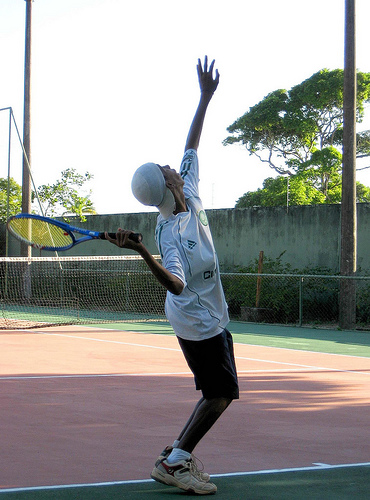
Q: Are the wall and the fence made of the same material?
A: No, the wall is made of cement and the fence is made of metal.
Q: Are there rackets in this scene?
A: Yes, there is a racket.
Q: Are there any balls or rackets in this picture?
A: Yes, there is a racket.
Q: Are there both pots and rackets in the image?
A: No, there is a racket but no pots.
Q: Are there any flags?
A: No, there are no flags.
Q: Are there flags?
A: No, there are no flags.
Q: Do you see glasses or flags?
A: No, there are no flags or glasses.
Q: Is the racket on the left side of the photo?
A: Yes, the racket is on the left of the image.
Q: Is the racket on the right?
A: No, the racket is on the left of the image.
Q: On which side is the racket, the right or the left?
A: The racket is on the left of the image.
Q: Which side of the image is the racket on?
A: The racket is on the left of the image.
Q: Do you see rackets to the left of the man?
A: Yes, there is a racket to the left of the man.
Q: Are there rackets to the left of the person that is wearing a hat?
A: Yes, there is a racket to the left of the man.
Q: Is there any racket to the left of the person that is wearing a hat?
A: Yes, there is a racket to the left of the man.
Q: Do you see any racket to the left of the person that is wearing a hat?
A: Yes, there is a racket to the left of the man.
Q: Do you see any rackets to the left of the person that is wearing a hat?
A: Yes, there is a racket to the left of the man.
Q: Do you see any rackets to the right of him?
A: No, the racket is to the left of the man.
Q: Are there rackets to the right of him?
A: No, the racket is to the left of the man.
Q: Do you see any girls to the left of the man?
A: No, there is a racket to the left of the man.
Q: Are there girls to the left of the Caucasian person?
A: No, there is a racket to the left of the man.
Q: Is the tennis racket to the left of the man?
A: Yes, the tennis racket is to the left of the man.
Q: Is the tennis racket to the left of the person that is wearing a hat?
A: Yes, the tennis racket is to the left of the man.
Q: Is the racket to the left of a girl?
A: No, the racket is to the left of the man.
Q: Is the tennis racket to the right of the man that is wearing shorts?
A: No, the tennis racket is to the left of the man.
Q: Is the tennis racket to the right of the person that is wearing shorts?
A: No, the tennis racket is to the left of the man.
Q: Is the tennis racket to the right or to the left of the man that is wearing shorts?
A: The tennis racket is to the left of the man.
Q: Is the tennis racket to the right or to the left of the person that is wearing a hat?
A: The tennis racket is to the left of the man.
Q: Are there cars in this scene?
A: No, there are no cars.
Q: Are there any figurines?
A: No, there are no figurines.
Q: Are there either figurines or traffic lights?
A: No, there are no figurines or traffic lights.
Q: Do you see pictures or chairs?
A: No, there are no pictures or chairs.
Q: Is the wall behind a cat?
A: No, the wall is behind the fence.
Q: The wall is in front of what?
A: The wall is in front of the tree.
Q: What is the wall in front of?
A: The wall is in front of the tree.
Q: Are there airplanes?
A: No, there are no airplanes.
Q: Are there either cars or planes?
A: No, there are no planes or cars.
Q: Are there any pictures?
A: No, there are no pictures.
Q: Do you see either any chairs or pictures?
A: No, there are no pictures or chairs.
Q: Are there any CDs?
A: No, there are no cds.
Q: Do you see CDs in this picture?
A: No, there are no cds.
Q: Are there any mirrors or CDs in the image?
A: No, there are no CDs or mirrors.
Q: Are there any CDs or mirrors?
A: No, there are no CDs or mirrors.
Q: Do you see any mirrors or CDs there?
A: No, there are no CDs or mirrors.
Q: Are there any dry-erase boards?
A: No, there are no dry-erase boards.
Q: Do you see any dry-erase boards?
A: No, there are no dry-erase boards.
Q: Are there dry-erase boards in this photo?
A: No, there are no dry-erase boards.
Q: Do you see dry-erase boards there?
A: No, there are no dry-erase boards.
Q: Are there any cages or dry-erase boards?
A: No, there are no dry-erase boards or cages.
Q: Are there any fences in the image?
A: Yes, there is a fence.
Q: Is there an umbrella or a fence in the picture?
A: Yes, there is a fence.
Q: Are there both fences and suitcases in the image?
A: No, there is a fence but no suitcases.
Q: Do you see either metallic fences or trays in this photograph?
A: Yes, there is a metal fence.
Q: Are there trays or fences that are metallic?
A: Yes, the fence is metallic.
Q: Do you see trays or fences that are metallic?
A: Yes, the fence is metallic.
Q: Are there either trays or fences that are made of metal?
A: Yes, the fence is made of metal.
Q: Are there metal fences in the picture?
A: Yes, there is a metal fence.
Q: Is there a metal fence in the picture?
A: Yes, there is a metal fence.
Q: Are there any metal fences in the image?
A: Yes, there is a metal fence.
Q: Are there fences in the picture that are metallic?
A: Yes, there is a fence that is metallic.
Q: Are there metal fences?
A: Yes, there is a fence that is made of metal.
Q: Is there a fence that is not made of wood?
A: Yes, there is a fence that is made of metal.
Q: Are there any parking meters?
A: No, there are no parking meters.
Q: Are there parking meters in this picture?
A: No, there are no parking meters.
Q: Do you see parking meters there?
A: No, there are no parking meters.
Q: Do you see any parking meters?
A: No, there are no parking meters.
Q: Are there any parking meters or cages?
A: No, there are no parking meters or cages.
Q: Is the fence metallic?
A: Yes, the fence is metallic.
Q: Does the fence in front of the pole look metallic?
A: Yes, the fence is metallic.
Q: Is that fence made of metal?
A: Yes, the fence is made of metal.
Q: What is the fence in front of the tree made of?
A: The fence is made of metal.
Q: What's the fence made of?
A: The fence is made of metal.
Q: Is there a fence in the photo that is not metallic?
A: No, there is a fence but it is metallic.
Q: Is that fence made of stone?
A: No, the fence is made of metal.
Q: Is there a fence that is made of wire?
A: No, there is a fence but it is made of metal.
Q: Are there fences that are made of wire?
A: No, there is a fence but it is made of metal.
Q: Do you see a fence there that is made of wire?
A: No, there is a fence but it is made of metal.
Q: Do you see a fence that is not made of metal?
A: No, there is a fence but it is made of metal.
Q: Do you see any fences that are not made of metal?
A: No, there is a fence but it is made of metal.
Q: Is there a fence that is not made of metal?
A: No, there is a fence but it is made of metal.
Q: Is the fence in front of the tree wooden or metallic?
A: The fence is metallic.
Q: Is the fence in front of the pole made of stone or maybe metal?
A: The fence is made of metal.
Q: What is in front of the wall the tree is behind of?
A: The fence is in front of the wall.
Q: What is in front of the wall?
A: The fence is in front of the wall.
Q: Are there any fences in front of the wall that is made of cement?
A: Yes, there is a fence in front of the wall.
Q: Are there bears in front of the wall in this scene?
A: No, there is a fence in front of the wall.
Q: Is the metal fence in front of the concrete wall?
A: Yes, the fence is in front of the wall.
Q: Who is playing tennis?
A: The man is playing tennis.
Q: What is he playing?
A: The man is playing tennis.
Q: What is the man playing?
A: The man is playing tennis.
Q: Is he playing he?
A: Yes, the man is playing tennis.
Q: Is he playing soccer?
A: No, the man is playing tennis.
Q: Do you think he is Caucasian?
A: Yes, the man is caucasian.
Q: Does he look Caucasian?
A: Yes, the man is caucasian.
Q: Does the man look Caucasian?
A: Yes, the man is caucasian.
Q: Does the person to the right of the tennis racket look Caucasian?
A: Yes, the man is caucasian.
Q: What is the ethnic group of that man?
A: The man is caucasian.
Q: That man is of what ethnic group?
A: The man is caucasian.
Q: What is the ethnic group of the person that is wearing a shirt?
A: The man is caucasian.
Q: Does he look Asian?
A: No, the man is caucasian.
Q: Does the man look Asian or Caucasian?
A: The man is caucasian.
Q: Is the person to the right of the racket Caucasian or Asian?
A: The man is caucasian.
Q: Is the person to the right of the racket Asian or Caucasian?
A: The man is caucasian.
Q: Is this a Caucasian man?
A: Yes, this is a Caucasian man.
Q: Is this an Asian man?
A: No, this is a Caucasian man.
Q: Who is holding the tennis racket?
A: The man is holding the tennis racket.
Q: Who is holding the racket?
A: The man is holding the tennis racket.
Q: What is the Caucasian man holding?
A: The man is holding the tennis racket.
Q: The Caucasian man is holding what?
A: The man is holding the tennis racket.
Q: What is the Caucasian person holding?
A: The man is holding the tennis racket.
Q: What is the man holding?
A: The man is holding the tennis racket.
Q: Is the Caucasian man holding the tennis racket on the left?
A: Yes, the man is holding the racket.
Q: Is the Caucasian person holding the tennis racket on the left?
A: Yes, the man is holding the racket.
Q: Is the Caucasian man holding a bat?
A: No, the man is holding the racket.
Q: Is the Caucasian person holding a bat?
A: No, the man is holding the racket.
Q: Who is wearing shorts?
A: The man is wearing shorts.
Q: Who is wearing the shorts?
A: The man is wearing shorts.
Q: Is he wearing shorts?
A: Yes, the man is wearing shorts.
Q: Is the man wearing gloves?
A: No, the man is wearing shorts.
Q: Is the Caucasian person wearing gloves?
A: No, the man is wearing shorts.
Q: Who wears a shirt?
A: The man wears a shirt.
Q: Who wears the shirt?
A: The man wears a shirt.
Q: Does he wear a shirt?
A: Yes, the man wears a shirt.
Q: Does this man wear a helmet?
A: No, the man wears a shirt.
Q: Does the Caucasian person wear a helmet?
A: No, the man wears a shirt.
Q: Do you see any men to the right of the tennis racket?
A: Yes, there is a man to the right of the tennis racket.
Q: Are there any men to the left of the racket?
A: No, the man is to the right of the racket.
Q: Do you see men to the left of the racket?
A: No, the man is to the right of the racket.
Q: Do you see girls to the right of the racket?
A: No, there is a man to the right of the racket.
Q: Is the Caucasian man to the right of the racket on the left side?
A: Yes, the man is to the right of the tennis racket.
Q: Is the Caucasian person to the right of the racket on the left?
A: Yes, the man is to the right of the tennis racket.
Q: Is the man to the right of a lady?
A: No, the man is to the right of the tennis racket.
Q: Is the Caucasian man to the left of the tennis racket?
A: No, the man is to the right of the tennis racket.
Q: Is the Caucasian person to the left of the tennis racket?
A: No, the man is to the right of the tennis racket.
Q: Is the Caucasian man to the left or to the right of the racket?
A: The man is to the right of the racket.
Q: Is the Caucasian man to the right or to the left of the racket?
A: The man is to the right of the racket.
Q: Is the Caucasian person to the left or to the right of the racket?
A: The man is to the right of the racket.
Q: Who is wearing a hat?
A: The man is wearing a hat.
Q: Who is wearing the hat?
A: The man is wearing a hat.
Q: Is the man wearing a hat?
A: Yes, the man is wearing a hat.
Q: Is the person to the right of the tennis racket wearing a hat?
A: Yes, the man is wearing a hat.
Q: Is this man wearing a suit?
A: No, the man is wearing a hat.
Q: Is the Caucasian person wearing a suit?
A: No, the man is wearing a hat.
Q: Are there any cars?
A: No, there are no cars.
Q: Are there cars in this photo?
A: No, there are no cars.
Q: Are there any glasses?
A: No, there are no glasses.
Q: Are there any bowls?
A: No, there are no bowls.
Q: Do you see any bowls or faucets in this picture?
A: No, there are no bowls or faucets.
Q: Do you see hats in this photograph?
A: Yes, there is a hat.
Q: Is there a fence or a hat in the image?
A: Yes, there is a hat.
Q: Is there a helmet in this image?
A: No, there are no helmets.